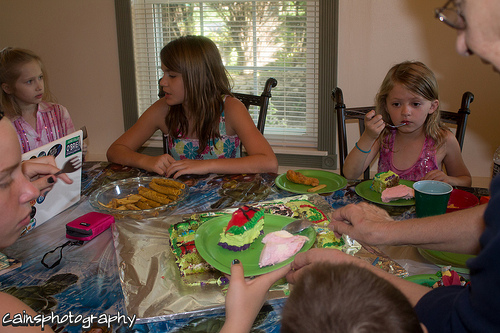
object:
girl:
[106, 34, 280, 181]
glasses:
[433, 0, 474, 32]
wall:
[0, 0, 499, 188]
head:
[276, 258, 428, 332]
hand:
[223, 258, 295, 319]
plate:
[191, 204, 316, 277]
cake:
[216, 200, 266, 251]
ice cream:
[258, 227, 309, 267]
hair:
[160, 37, 236, 154]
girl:
[342, 60, 473, 187]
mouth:
[396, 118, 414, 124]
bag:
[65, 211, 114, 241]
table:
[0, 159, 499, 332]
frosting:
[222, 203, 260, 243]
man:
[286, 0, 500, 332]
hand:
[325, 201, 393, 244]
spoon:
[283, 217, 336, 233]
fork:
[365, 116, 410, 128]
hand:
[358, 110, 387, 141]